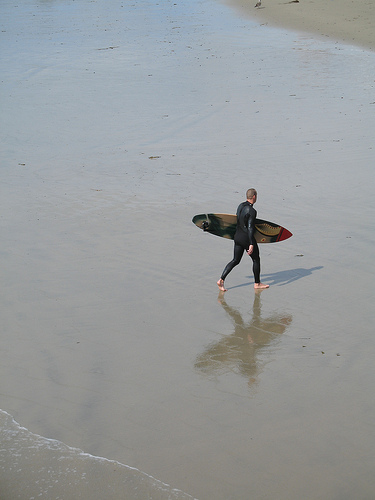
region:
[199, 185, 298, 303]
this is a surfing guy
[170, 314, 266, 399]
this is the water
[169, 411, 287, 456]
the water is colourless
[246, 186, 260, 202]
this is the head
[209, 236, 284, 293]
these are the legs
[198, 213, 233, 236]
these is the surfing board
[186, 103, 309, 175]
the water is colourless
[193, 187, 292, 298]
the surfer is walking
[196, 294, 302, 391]
this is the shadow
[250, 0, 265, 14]
this is the birds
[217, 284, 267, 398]
reflection of man on wet sand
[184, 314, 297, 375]
reflection of surfboard on wet sand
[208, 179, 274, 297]
surfer wearing wetsuit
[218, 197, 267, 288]
wetsuit is color black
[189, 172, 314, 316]
surfer walks on wet sand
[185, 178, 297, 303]
surfer holds a surfboard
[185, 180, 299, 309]
surfboard under left arm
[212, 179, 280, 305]
surfer is bare feet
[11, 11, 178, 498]
the sand is wet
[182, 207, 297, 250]
surfboard is color yellow, black and red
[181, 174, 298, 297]
A man holding a surfboard by the sea shore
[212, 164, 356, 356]
a man is walking in water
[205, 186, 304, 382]
man is caribg a surfboad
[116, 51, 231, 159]
the water is calm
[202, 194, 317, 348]
man is walking away from the water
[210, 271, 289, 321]
man does not have shoes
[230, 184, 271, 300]
man is dressed in black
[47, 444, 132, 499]
the water is colorles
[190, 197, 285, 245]
the surfboard is multicolored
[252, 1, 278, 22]
birds are near the water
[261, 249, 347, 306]
the man shadow is in water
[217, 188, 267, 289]
the man walking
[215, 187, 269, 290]
the man wearing a wet suit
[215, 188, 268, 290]
the man wearing all black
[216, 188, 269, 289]
the man carrying the surfboard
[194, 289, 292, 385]
the reflection on the wet sand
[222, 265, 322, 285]
the shadow on the ground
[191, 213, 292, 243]
the surfboard the man is carrying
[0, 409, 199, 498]
the shallow ocean water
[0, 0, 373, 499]
the large area of wet sand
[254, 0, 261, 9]
the bird on the sand